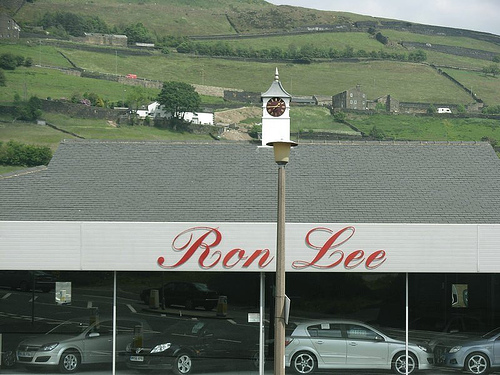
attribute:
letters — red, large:
[153, 225, 389, 276]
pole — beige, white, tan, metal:
[265, 137, 298, 372]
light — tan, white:
[262, 140, 299, 168]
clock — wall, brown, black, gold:
[265, 92, 288, 118]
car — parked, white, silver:
[281, 317, 439, 375]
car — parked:
[12, 316, 139, 375]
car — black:
[121, 306, 268, 374]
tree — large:
[151, 75, 204, 128]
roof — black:
[2, 138, 499, 221]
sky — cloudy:
[318, 3, 499, 28]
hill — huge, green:
[8, 2, 499, 106]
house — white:
[134, 97, 220, 128]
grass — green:
[3, 4, 499, 148]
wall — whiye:
[184, 113, 212, 124]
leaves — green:
[155, 79, 207, 113]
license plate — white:
[125, 354, 146, 364]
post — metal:
[272, 161, 288, 374]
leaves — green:
[36, 30, 342, 158]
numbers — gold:
[257, 82, 292, 127]